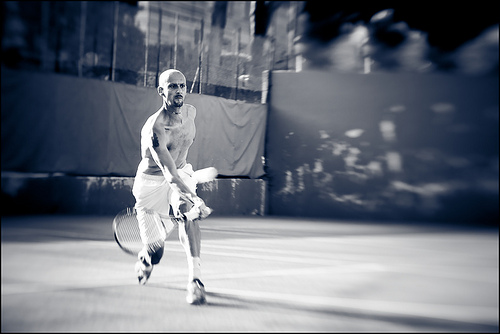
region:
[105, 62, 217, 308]
a shirtless tennis player in motion while hitting a ball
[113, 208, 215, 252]
a tennis racket being used to hit the tennis ball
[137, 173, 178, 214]
white shorts being worn by the man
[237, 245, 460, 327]
a tennis court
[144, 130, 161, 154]
a tattoo on the man's arm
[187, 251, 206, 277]
white socks being worn by the man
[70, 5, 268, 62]
a fence in the background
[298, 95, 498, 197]
a worn-out wall by the tennis court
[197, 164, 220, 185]
a tennis ball being struck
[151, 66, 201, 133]
a focused expression on the tennis player's face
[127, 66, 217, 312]
male tennis player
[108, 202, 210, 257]
tennis racket being held by a tennis player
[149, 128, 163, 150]
tennis player has a tattoo on his upper right arm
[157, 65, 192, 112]
tennis player's face looks concentrated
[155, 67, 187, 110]
tennis player has a bald head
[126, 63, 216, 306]
tennis player is not wearing a shirt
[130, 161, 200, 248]
tennis player wears white shorts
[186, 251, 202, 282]
white sock on a tennis player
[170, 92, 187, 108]
tennis player has a beard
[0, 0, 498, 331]
the image is black and white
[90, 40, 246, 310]
The man is playing tennis.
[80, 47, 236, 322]
The man is holding a tennis racket in his right hand.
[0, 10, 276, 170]
A large fence that is half covered.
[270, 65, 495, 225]
A wall.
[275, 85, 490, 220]
White markings are on the wall.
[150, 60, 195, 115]
The man is bald.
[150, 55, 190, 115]
The man has a goatee.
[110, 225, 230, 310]
The man is wearing sneakers.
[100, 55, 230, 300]
The man is moving to hit a ball.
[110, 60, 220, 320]
The man is wearing white shorts.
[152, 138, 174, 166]
part of a bicep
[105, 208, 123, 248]
edge of a racket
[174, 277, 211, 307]
part of a shoe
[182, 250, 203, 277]
part of a sock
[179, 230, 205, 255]
part of a leg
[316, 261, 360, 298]
part of the tennis court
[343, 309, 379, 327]
part of a shade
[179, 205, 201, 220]
handle of a racket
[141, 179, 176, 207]
part of a short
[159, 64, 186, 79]
part of a head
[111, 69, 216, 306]
a man playing tennis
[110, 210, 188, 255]
a wide face tennis racket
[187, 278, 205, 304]
a pair of white and black tennis shoes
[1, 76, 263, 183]
a wind screen on the chain link fence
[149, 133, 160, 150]
the man has a tattoo on his right upper arm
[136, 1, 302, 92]
tall buildings are seen in the distance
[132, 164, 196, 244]
the man is wearing white tennis shorts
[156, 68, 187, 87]
the tennis player has a bald head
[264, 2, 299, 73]
a tall tree behind the fence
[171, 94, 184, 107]
the man has a a mustache and a goatee